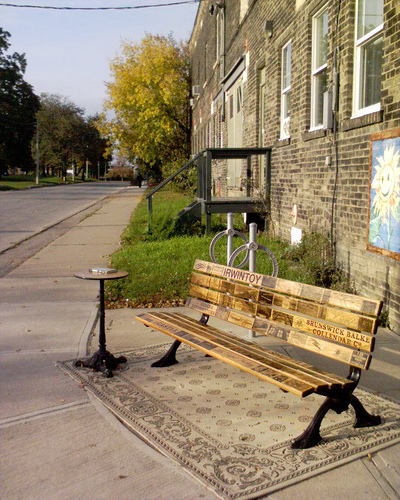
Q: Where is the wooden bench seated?
A: Street corner.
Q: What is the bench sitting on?
A: Brown and white rug.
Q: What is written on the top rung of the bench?
A: Irwintoy.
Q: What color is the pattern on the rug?
A: Brown.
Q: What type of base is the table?
A: Cast iron.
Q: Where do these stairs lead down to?
A: The sidewalk.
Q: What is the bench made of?
A: Wood and metal.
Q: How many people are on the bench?
A: 0.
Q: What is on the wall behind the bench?
A: Painting of an animated sunflower.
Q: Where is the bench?
A: On the corner.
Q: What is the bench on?
A: A rug.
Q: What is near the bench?
A: A small table.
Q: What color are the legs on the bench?
A: Black.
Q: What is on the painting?
A: The sun.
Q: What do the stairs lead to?
A: The entrance.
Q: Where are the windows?
A: On the building.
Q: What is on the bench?
A: A design.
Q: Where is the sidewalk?
A: Next to the street.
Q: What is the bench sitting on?
A: A rug.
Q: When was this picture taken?
A: During the day.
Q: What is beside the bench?
A: A table.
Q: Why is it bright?
A: It's day light.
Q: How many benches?
A: One.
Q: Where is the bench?
A: Outside of the building.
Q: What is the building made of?
A: Bricks.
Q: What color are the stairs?
A: Black.